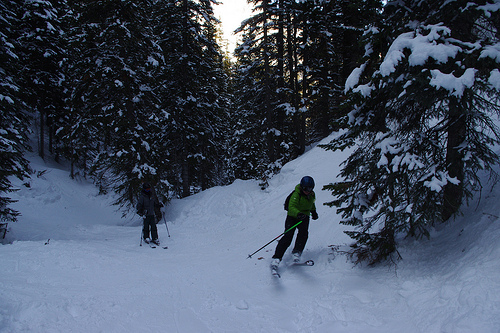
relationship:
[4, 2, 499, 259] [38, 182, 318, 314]
forest covered in snow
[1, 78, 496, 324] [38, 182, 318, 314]
mountain filled with snow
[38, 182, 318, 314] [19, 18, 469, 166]
snow on trees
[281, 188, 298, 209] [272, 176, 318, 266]
backpack on skiers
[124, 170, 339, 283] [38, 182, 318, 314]
skiers are on snow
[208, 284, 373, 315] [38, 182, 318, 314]
tracks are in snow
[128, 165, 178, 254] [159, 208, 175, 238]
person hold ski pole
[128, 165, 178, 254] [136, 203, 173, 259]
person on skis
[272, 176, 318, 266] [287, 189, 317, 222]
skiers wears jacket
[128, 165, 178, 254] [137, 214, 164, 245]
person wears pants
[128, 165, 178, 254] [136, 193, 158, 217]
person wears black outfit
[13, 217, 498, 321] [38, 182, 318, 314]
ground covered in snow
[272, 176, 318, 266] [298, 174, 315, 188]
skiers wears helmet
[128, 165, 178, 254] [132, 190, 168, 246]
person wears black outfit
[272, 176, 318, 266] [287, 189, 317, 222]
skiers in jacket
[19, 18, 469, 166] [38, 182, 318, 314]
trees are in snow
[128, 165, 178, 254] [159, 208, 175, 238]
person holds ski pole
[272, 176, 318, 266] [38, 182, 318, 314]
skiers in snow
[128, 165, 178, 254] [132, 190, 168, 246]
person wearing black outfit